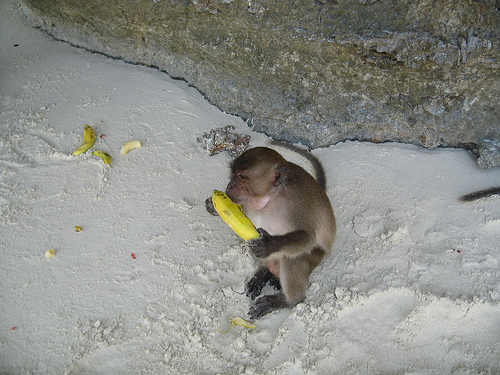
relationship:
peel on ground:
[72, 123, 112, 165] [1, 0, 497, 373]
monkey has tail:
[205, 131, 340, 321] [267, 135, 334, 189]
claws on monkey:
[244, 267, 279, 320] [205, 131, 340, 321]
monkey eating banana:
[205, 131, 340, 321] [212, 188, 262, 245]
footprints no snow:
[103, 256, 230, 336] [16, 67, 493, 353]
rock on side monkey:
[326, 18, 473, 135] [205, 131, 340, 321]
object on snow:
[193, 122, 250, 166] [8, 17, 496, 364]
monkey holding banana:
[218, 123, 350, 326] [202, 179, 274, 254]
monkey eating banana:
[237, 160, 329, 304] [207, 185, 257, 240]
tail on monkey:
[276, 136, 330, 184] [227, 138, 327, 314]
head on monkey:
[225, 146, 288, 206] [208, 145, 340, 310]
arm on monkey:
[245, 225, 315, 257] [205, 131, 340, 321]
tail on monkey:
[267, 138, 326, 189] [205, 131, 340, 321]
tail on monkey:
[258, 127, 342, 195] [205, 138, 341, 337]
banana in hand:
[212, 188, 262, 245] [200, 195, 220, 215]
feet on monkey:
[245, 266, 280, 317] [213, 128, 344, 318]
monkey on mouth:
[192, 133, 358, 323] [224, 190, 243, 205]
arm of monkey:
[246, 219, 341, 270] [236, 129, 396, 311]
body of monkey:
[238, 165, 338, 260] [196, 137, 336, 319]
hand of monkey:
[240, 225, 325, 259] [205, 131, 340, 321]